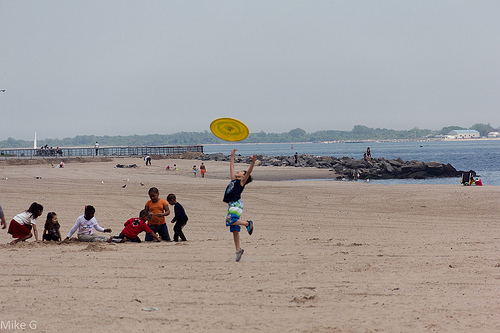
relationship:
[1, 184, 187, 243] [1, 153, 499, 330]
people on beach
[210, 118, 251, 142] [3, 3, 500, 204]
frisbee in air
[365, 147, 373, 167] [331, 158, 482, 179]
girl sitting on rocks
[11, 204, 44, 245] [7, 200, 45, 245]
person bending person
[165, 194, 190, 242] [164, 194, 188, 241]
person bending over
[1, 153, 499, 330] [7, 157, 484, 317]
sand on beach